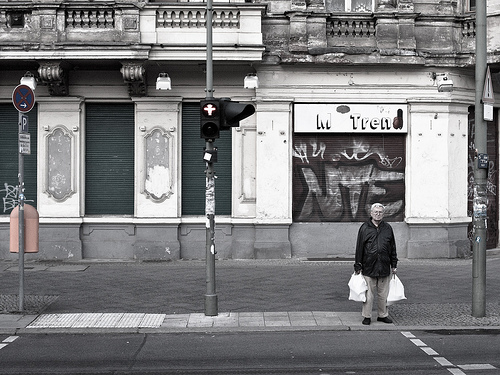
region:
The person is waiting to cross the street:
[16, 30, 476, 365]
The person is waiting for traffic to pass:
[7, 36, 497, 368]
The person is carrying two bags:
[298, 165, 441, 347]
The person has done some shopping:
[292, 132, 458, 347]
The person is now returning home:
[295, 132, 470, 347]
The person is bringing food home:
[267, 133, 473, 353]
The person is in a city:
[20, 45, 481, 361]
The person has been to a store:
[17, 23, 485, 356]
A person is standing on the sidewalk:
[310, 145, 450, 351]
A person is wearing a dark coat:
[340, 189, 419, 335]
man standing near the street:
[325, 189, 426, 333]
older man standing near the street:
[325, 183, 426, 334]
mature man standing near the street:
[298, 179, 438, 341]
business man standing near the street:
[316, 174, 436, 356]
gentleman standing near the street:
[325, 180, 424, 352]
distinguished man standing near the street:
[322, 156, 437, 361]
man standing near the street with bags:
[330, 175, 422, 340]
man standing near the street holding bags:
[302, 171, 424, 347]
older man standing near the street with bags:
[311, 175, 431, 353]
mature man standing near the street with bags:
[330, 173, 434, 351]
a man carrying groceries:
[345, 202, 407, 325]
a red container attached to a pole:
[7, 202, 42, 253]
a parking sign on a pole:
[18, 114, 30, 131]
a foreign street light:
[203, 95, 260, 141]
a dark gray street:
[0, 330, 497, 372]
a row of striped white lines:
[403, 328, 490, 373]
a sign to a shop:
[293, 104, 407, 131]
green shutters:
[83, 100, 133, 215]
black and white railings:
[0, 5, 263, 43]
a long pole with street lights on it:
[200, 0, 224, 313]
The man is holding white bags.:
[350, 200, 405, 324]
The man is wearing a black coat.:
[346, 201, 401, 324]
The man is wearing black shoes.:
[347, 200, 405, 328]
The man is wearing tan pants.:
[347, 198, 399, 323]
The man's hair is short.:
[368, 203, 386, 220]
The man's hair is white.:
[368, 201, 385, 223]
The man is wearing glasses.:
[370, 199, 386, 221]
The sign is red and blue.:
[12, 79, 35, 116]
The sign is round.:
[13, 83, 38, 114]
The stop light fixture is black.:
[198, 93, 253, 144]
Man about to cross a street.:
[345, 200, 406, 333]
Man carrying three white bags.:
[345, 200, 405, 335]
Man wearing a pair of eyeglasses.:
[367, 206, 387, 216]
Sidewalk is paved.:
[90, 260, 350, 305]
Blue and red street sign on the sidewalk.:
[7, 80, 37, 111]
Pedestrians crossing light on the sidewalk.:
[191, 95, 222, 145]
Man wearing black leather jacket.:
[350, 220, 399, 280]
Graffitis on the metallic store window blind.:
[292, 135, 398, 215]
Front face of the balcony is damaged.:
[265, 1, 490, 71]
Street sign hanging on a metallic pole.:
[6, 80, 41, 315]